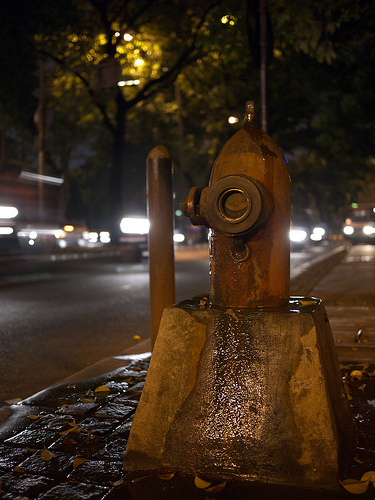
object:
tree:
[282, 7, 374, 232]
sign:
[83, 49, 126, 98]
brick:
[42, 480, 110, 497]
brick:
[2, 466, 50, 499]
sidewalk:
[6, 344, 131, 499]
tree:
[20, 51, 93, 235]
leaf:
[69, 453, 90, 471]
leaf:
[25, 412, 39, 420]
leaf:
[51, 413, 82, 438]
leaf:
[348, 368, 364, 381]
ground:
[343, 250, 375, 273]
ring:
[229, 239, 253, 265]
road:
[2, 232, 143, 431]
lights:
[115, 33, 163, 90]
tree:
[37, 0, 215, 249]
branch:
[35, 45, 115, 135]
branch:
[98, 11, 124, 103]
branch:
[129, 8, 219, 110]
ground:
[337, 277, 372, 319]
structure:
[119, 92, 354, 492]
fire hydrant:
[179, 101, 296, 307]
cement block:
[122, 292, 362, 489]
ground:
[19, 286, 106, 327]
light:
[117, 212, 151, 233]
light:
[22, 225, 43, 246]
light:
[62, 220, 83, 233]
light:
[0, 227, 20, 240]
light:
[2, 203, 20, 223]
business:
[2, 138, 69, 246]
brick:
[8, 407, 61, 445]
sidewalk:
[287, 236, 346, 310]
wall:
[20, 189, 39, 218]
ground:
[3, 324, 62, 364]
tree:
[166, 64, 207, 185]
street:
[159, 124, 370, 485]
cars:
[287, 210, 328, 258]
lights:
[172, 228, 188, 251]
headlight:
[340, 222, 354, 236]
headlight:
[362, 222, 374, 234]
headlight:
[289, 223, 307, 243]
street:
[1, 87, 236, 404]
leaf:
[337, 477, 372, 494]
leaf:
[188, 471, 210, 488]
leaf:
[40, 443, 52, 461]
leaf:
[93, 385, 110, 395]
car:
[81, 223, 113, 249]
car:
[340, 206, 374, 241]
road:
[293, 223, 375, 408]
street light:
[113, 27, 135, 47]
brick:
[124, 375, 151, 391]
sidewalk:
[1, 253, 373, 491]